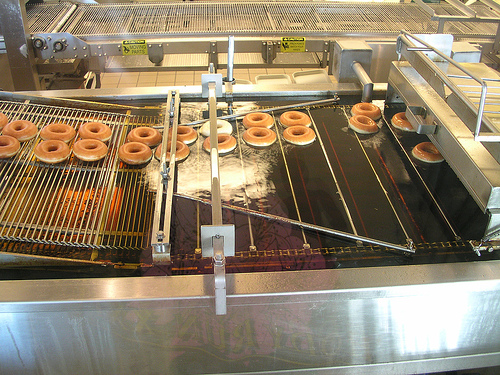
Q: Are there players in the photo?
A: No, there are no players.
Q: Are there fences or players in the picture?
A: No, there are no players or fences.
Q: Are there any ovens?
A: Yes, there is an oven.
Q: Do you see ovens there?
A: Yes, there is an oven.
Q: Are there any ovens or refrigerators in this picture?
A: Yes, there is an oven.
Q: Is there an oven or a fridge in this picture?
A: Yes, there is an oven.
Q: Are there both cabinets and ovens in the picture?
A: No, there is an oven but no cabinets.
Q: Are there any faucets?
A: No, there are no faucets.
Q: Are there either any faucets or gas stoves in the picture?
A: No, there are no faucets or gas stoves.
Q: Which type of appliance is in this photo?
A: The appliance is an oven.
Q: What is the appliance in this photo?
A: The appliance is an oven.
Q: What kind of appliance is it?
A: The appliance is an oven.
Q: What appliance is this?
A: That is an oven.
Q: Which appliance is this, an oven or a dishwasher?
A: That is an oven.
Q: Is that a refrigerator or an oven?
A: That is an oven.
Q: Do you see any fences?
A: No, there are no fences.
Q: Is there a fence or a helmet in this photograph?
A: No, there are no fences or helmets.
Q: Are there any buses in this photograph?
A: No, there are no buses.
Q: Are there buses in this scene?
A: No, there are no buses.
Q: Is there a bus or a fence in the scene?
A: No, there are no buses or fences.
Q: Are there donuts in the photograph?
A: Yes, there are donuts.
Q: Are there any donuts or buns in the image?
A: Yes, there are donuts.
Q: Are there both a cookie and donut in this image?
A: No, there are donuts but no cookies.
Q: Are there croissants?
A: No, there are no croissants.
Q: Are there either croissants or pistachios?
A: No, there are no croissants or pistachios.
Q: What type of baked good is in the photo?
A: The baked good is donuts.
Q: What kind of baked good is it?
A: The food is donuts.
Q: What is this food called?
A: These are donuts.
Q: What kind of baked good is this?
A: These are donuts.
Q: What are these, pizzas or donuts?
A: These are donuts.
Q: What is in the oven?
A: The donuts are in the oven.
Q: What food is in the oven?
A: The food is donuts.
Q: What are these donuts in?
A: The donuts are in the oven.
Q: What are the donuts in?
A: The donuts are in the oven.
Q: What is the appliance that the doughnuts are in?
A: The appliance is an oven.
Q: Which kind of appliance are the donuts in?
A: The doughnuts are in the oven.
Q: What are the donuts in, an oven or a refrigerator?
A: The donuts are in an oven.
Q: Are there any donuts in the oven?
A: Yes, there are donuts in the oven.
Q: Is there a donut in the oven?
A: Yes, there are donuts in the oven.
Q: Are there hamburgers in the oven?
A: No, there are donuts in the oven.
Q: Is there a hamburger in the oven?
A: No, there are donuts in the oven.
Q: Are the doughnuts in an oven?
A: Yes, the doughnuts are in an oven.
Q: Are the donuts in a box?
A: No, the donuts are in an oven.